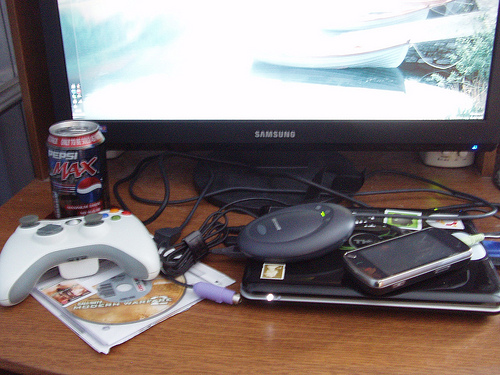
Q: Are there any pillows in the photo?
A: No, there are no pillows.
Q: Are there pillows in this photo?
A: No, there are no pillows.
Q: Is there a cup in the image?
A: No, there are no cups.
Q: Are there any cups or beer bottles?
A: No, there are no cups or beer bottles.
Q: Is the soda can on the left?
A: Yes, the soda can is on the left of the image.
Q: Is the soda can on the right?
A: No, the soda can is on the left of the image.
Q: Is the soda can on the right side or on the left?
A: The soda can is on the left of the image.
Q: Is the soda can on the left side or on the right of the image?
A: The soda can is on the left of the image.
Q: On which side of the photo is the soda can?
A: The soda can is on the left of the image.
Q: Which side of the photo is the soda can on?
A: The soda can is on the left of the image.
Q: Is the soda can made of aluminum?
A: Yes, the soda can is made of aluminum.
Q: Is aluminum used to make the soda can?
A: Yes, the soda can is made of aluminum.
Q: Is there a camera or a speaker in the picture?
A: No, there are no cameras or speakers.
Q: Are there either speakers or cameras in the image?
A: No, there are no cameras or speakers.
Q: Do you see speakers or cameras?
A: No, there are no cameras or speakers.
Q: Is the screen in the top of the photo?
A: Yes, the screen is in the top of the image.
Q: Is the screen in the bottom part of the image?
A: No, the screen is in the top of the image.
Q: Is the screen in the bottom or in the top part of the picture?
A: The screen is in the top of the image.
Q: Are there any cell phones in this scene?
A: Yes, there is a cell phone.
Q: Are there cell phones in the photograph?
A: Yes, there is a cell phone.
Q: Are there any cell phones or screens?
A: Yes, there is a cell phone.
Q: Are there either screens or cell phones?
A: Yes, there is a cell phone.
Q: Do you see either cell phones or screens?
A: Yes, there is a cell phone.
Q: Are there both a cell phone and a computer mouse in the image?
A: Yes, there are both a cell phone and a computer mouse.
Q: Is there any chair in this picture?
A: No, there are no chairs.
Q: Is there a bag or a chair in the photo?
A: No, there are no chairs or bags.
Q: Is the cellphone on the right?
A: Yes, the cellphone is on the right of the image.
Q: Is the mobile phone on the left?
A: No, the mobile phone is on the right of the image.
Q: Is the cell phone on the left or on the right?
A: The cell phone is on the right of the image.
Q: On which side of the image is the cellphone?
A: The cellphone is on the right of the image.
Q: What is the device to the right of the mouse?
A: The device is a cell phone.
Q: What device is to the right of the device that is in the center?
A: The device is a cell phone.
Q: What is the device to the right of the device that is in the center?
A: The device is a cell phone.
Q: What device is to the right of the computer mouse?
A: The device is a cell phone.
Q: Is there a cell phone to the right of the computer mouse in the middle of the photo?
A: Yes, there is a cell phone to the right of the computer mouse.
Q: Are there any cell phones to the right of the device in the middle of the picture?
A: Yes, there is a cell phone to the right of the computer mouse.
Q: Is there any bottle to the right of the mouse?
A: No, there is a cell phone to the right of the mouse.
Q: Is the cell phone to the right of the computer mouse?
A: Yes, the cell phone is to the right of the computer mouse.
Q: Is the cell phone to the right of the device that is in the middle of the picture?
A: Yes, the cell phone is to the right of the computer mouse.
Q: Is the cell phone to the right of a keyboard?
A: No, the cell phone is to the right of the computer mouse.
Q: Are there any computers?
A: Yes, there is a computer.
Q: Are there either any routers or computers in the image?
A: Yes, there is a computer.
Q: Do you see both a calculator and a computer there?
A: No, there is a computer but no calculators.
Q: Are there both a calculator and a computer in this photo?
A: No, there is a computer but no calculators.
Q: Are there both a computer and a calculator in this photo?
A: No, there is a computer but no calculators.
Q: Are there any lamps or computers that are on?
A: Yes, the computer is on.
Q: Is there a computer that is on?
A: Yes, there is a computer that is on.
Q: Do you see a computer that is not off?
A: Yes, there is a computer that is on .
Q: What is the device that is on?
A: The device is a computer.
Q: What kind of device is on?
A: The device is a computer.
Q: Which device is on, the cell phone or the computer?
A: The computer is on.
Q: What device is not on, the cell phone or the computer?
A: The cell phone is not on.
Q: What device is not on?
A: The device is a cell phone.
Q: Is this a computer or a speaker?
A: This is a computer.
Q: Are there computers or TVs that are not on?
A: No, there is a computer but it is on.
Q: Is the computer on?
A: Yes, the computer is on.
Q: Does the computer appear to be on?
A: Yes, the computer is on.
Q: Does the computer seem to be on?
A: Yes, the computer is on.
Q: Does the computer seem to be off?
A: No, the computer is on.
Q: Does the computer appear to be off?
A: No, the computer is on.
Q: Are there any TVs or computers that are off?
A: No, there is a computer but it is on.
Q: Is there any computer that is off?
A: No, there is a computer but it is on.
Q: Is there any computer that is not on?
A: No, there is a computer but it is on.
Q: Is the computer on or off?
A: The computer is on.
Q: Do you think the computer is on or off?
A: The computer is on.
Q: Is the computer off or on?
A: The computer is on.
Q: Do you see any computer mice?
A: Yes, there is a computer mouse.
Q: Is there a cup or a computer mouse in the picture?
A: Yes, there is a computer mouse.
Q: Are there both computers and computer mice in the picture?
A: Yes, there are both a computer mouse and a computer.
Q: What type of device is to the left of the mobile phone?
A: The device is a computer mouse.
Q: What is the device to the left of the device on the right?
A: The device is a computer mouse.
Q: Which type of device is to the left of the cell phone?
A: The device is a computer mouse.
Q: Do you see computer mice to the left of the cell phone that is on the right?
A: Yes, there is a computer mouse to the left of the mobile phone.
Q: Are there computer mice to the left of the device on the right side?
A: Yes, there is a computer mouse to the left of the mobile phone.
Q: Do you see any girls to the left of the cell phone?
A: No, there is a computer mouse to the left of the cell phone.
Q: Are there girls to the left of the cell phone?
A: No, there is a computer mouse to the left of the cell phone.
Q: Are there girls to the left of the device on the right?
A: No, there is a computer mouse to the left of the cell phone.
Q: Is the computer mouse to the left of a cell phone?
A: Yes, the computer mouse is to the left of a cell phone.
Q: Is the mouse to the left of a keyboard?
A: No, the mouse is to the left of a cell phone.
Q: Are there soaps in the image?
A: No, there are no soaps.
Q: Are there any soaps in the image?
A: No, there are no soaps.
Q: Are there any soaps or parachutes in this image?
A: No, there are no soaps or parachutes.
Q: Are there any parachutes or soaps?
A: No, there are no soaps or parachutes.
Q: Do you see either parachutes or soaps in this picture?
A: No, there are no soaps or parachutes.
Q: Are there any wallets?
A: No, there are no wallets.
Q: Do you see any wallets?
A: No, there are no wallets.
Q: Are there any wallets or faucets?
A: No, there are no wallets or faucets.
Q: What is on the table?
A: The wires are on the table.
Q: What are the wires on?
A: The wires are on the table.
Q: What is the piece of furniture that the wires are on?
A: The piece of furniture is a table.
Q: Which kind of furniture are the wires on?
A: The wires are on the table.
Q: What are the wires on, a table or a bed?
A: The wires are on a table.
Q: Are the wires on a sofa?
A: No, the wires are on the table.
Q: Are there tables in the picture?
A: Yes, there is a table.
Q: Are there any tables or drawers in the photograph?
A: Yes, there is a table.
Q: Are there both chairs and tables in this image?
A: No, there is a table but no chairs.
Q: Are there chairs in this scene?
A: No, there are no chairs.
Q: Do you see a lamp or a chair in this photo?
A: No, there are no chairs or lamps.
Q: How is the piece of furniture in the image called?
A: The piece of furniture is a table.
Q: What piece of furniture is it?
A: The piece of furniture is a table.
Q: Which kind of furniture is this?
A: This is a table.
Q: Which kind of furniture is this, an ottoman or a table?
A: This is a table.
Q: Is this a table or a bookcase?
A: This is a table.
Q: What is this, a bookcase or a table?
A: This is a table.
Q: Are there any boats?
A: Yes, there is a boat.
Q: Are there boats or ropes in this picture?
A: Yes, there is a boat.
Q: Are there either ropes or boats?
A: Yes, there is a boat.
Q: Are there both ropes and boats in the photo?
A: No, there is a boat but no ropes.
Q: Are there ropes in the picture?
A: No, there are no ropes.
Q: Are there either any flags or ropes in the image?
A: No, there are no ropes or flags.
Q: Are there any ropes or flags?
A: No, there are no ropes or flags.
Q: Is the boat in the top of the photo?
A: Yes, the boat is in the top of the image.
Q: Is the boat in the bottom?
A: No, the boat is in the top of the image.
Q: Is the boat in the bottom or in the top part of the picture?
A: The boat is in the top of the image.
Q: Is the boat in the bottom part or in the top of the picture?
A: The boat is in the top of the image.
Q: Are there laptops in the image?
A: Yes, there is a laptop.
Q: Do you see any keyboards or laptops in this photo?
A: Yes, there is a laptop.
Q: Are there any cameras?
A: No, there are no cameras.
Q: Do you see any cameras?
A: No, there are no cameras.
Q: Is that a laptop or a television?
A: That is a laptop.